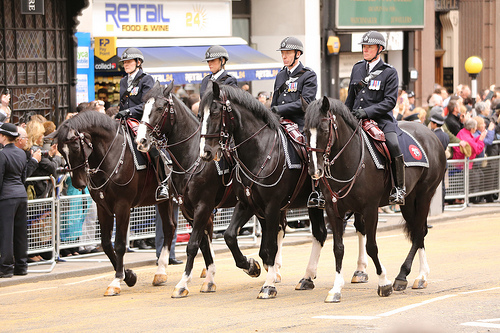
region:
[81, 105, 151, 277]
black horse on dirt road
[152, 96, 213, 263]
black horse on dirt road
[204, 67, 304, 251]
black horse on dirt road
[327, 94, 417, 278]
black horse on dirt road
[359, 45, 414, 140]
police officer on horse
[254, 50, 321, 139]
police officer on horse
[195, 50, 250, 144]
police officer on horse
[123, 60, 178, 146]
police officer on horse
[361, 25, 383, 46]
helmet on police officer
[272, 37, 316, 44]
helmet on police officer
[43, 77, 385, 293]
view is a horse race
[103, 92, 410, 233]
horses are black in color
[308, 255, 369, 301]
the legs are white in color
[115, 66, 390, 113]
men are dressed in same outfit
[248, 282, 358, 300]
hoofs are balck in color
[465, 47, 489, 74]
globe street light is yellow in color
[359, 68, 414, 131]
the outfit ids blck in color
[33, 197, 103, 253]
the fence is white in color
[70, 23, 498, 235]
People riding on the horses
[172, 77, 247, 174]
Horse is wearing a bridle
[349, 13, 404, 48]
Rider is wearing a helmet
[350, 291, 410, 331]
Paint on the road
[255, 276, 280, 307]
The hoof is black and white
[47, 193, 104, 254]
Fence in front of the crowd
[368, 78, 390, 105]
Patch on front of blazer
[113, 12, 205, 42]
Sign over the business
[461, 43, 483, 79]
Light on top of pole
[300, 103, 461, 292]
A beautiful black horse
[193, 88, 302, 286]
A beautiful black horse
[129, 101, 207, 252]
A beautiful black horse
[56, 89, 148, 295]
A beautiful black horse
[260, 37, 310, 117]
A person on a horse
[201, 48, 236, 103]
A person on a horse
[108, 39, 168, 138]
A person on a horse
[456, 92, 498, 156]
people on the fance staring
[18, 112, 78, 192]
people on the fance staring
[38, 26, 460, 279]
People on the horses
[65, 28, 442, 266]
Group of people on horses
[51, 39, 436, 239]
Cops on top of horses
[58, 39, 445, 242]
Police on top of horses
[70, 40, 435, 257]
Men on top of horses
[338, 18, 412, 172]
Man wearing black jacket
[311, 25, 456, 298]
Man on brown horse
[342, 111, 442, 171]
Black saddle on horse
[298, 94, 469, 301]
Horse walking down street